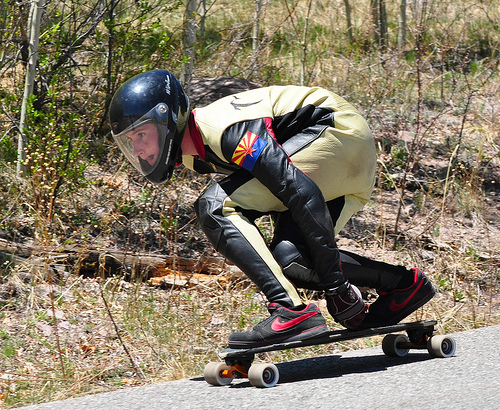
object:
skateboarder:
[108, 69, 436, 350]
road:
[336, 356, 496, 409]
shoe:
[227, 302, 328, 349]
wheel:
[247, 361, 279, 389]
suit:
[180, 83, 405, 307]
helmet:
[108, 68, 187, 185]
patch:
[231, 130, 270, 172]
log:
[0, 237, 248, 288]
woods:
[1, 9, 102, 259]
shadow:
[281, 350, 415, 382]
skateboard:
[204, 320, 456, 386]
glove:
[322, 286, 370, 328]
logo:
[269, 310, 318, 331]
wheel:
[202, 360, 234, 385]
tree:
[170, 4, 226, 79]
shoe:
[359, 268, 436, 324]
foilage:
[13, 294, 203, 378]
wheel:
[426, 334, 455, 357]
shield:
[111, 103, 169, 177]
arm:
[219, 116, 343, 280]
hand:
[324, 283, 369, 329]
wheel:
[381, 333, 413, 358]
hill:
[308, 32, 486, 81]